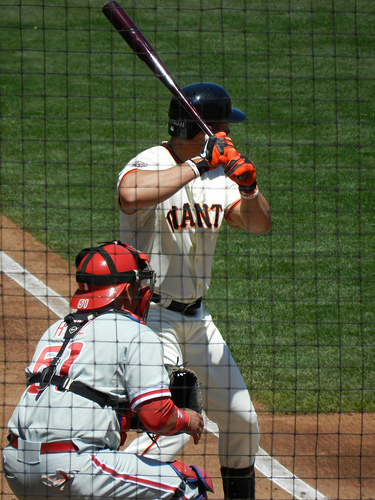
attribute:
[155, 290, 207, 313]
belt — black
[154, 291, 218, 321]
belt — black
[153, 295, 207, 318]
belt — black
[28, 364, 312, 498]
box — batter's 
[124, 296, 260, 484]
pants — white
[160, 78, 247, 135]
helmet — black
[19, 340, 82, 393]
number — jersey, 61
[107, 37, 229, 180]
bat — wooden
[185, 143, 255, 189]
gloves — orange, black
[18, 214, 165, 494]
catcher — crouched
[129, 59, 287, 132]
helmet — black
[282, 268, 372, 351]
grass — green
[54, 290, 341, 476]
line — white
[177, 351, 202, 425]
mitt — black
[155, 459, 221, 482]
shinguard — red, blue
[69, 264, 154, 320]
mask — red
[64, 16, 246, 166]
bat — held, wooden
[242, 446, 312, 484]
line — white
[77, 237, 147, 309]
helmet — red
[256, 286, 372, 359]
grass — green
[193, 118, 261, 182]
gloves — black, orange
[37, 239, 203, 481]
catcher — crouched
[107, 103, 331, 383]
batter — poised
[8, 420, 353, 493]
dirt — brown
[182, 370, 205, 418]
mitt — black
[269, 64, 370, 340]
grass — green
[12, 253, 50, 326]
line — white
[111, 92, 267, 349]
batter — poised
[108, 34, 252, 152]
bat — wooden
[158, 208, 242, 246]
logo — black, orange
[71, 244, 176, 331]
helmet — red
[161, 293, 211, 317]
belt — black